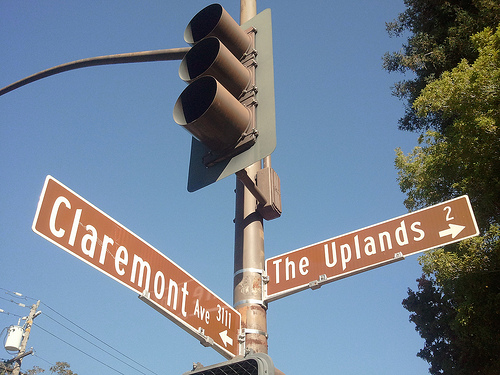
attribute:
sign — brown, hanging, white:
[30, 175, 240, 358]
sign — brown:
[261, 195, 481, 308]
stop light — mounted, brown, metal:
[168, 2, 283, 194]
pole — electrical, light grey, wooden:
[9, 296, 43, 374]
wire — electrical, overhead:
[42, 302, 156, 374]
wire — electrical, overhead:
[41, 310, 146, 374]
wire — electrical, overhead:
[34, 322, 123, 374]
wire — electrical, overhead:
[32, 353, 68, 374]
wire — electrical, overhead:
[3, 296, 24, 308]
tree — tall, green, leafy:
[391, 62, 499, 346]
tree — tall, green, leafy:
[383, 1, 499, 137]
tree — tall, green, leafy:
[401, 272, 483, 374]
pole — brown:
[235, 3, 269, 362]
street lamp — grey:
[0, 45, 194, 98]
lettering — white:
[270, 203, 455, 287]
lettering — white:
[47, 193, 235, 337]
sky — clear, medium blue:
[0, 1, 488, 372]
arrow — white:
[218, 326, 236, 352]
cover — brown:
[170, 73, 250, 154]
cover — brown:
[175, 36, 252, 100]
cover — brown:
[182, 1, 255, 61]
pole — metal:
[3, 44, 192, 107]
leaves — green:
[379, 47, 414, 74]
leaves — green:
[408, 58, 474, 116]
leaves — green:
[403, 285, 427, 319]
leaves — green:
[466, 24, 498, 62]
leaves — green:
[381, 13, 408, 40]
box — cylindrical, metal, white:
[3, 323, 25, 356]